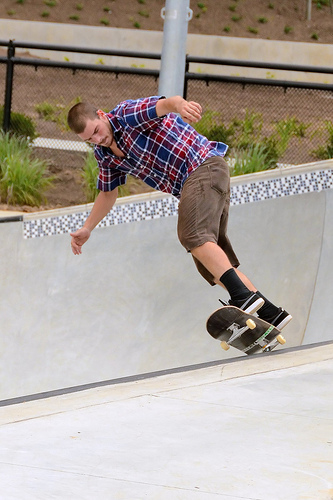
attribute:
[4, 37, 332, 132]
fence — black, small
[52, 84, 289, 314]
man — looking, skating, white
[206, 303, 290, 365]
board — black, long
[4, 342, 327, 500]
ground — grey, thick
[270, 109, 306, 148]
bush — green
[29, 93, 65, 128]
bush — green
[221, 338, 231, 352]
wheel — white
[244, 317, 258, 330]
wheel — white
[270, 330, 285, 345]
wheel — white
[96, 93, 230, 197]
shirt — short sleeve, plaid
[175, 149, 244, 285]
shorts — long, brown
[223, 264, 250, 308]
socks — black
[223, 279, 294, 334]
shoes — black, white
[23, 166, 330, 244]
tile trim — black, white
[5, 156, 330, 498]
pool — concrete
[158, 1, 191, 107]
pole — silver